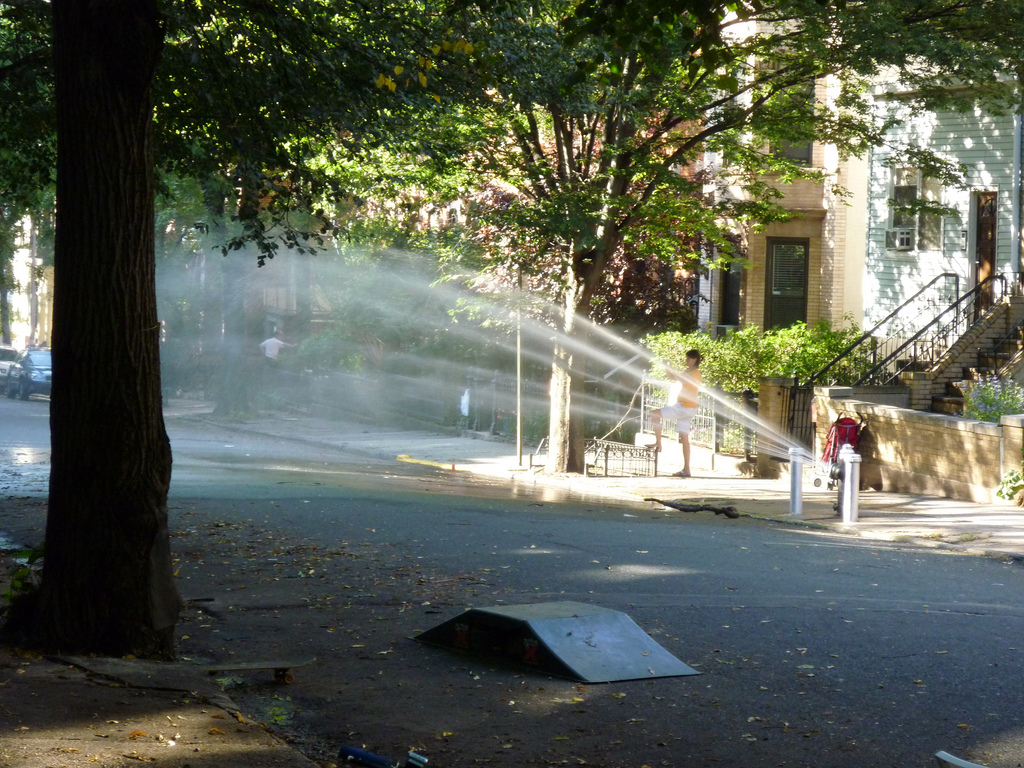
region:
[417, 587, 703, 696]
a small ramp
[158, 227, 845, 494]
water coming out of the hydrant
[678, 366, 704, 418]
a peach shirt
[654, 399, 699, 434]
a pair of shorts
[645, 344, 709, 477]
a person standing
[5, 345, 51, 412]
the cars parked on the street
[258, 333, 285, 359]
a white shirt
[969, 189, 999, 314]
a wooden door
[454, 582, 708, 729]
the ramp is metal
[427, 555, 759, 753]
ramp is on the road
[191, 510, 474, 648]
the leaves are on the road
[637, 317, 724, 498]
the woman is behind the water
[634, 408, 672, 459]
leg is on the bench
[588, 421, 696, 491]
bench is on the sidewalk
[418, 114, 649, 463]
tree is on the sidewalk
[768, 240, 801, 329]
glass window in the building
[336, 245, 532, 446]
water spraying from fire hydrant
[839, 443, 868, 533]
water spraying from fire hydrant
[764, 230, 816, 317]
brown door of town house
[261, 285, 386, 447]
water spraying in street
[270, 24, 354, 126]
green leaves on brown tree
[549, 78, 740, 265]
green leaves on brown tree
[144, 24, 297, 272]
green leaves on brown tree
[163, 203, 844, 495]
a long spray of water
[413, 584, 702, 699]
a small skateboarding ramp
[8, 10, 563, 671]
a large shade tree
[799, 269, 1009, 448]
a black metal handrail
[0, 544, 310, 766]
a cement sidewalk in the shade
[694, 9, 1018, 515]
a white painted apartment building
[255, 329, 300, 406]
a person in a white shirt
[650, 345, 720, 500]
a person in an orange shirt and white shorts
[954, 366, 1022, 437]
a shrub with purple flowers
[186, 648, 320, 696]
Discarded skateboard in street.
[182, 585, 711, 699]
Skateboard and ramp standing in street.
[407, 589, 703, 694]
Improvised gray metal ramp.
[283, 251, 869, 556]
water spraying from hydrant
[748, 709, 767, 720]
A leaf on the ground.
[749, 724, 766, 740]
A leaf on the ground.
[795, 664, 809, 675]
A leaf on the ground.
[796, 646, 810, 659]
A leaf on the ground.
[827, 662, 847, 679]
A leaf on the ground.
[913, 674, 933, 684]
A leaf on the ground.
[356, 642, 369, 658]
A leaf on the ground.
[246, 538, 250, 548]
A leaf on the ground.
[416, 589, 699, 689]
wooden bike ramp on street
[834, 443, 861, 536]
white post on sidewalk near fire hydrant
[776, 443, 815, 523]
white post on sidewalk near fire hydrant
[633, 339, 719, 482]
person standing behind spray of water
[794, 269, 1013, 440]
stairs leading up into a building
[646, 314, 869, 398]
green shrubbery behind a person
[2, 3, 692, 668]
large tree shading the street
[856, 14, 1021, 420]
white building behind a person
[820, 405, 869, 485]
baby stroller parked near brick wall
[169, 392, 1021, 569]
sidewalk along a road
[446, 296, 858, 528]
Water is spraying out of the fire hydrant.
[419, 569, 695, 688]
An skateboard ramp was left in the road.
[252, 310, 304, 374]
A man wearing a white shirt.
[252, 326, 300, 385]
A man standing outside.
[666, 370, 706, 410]
A woman wearing a yellow shirt.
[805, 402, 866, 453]
A red carriage left close to the wall.